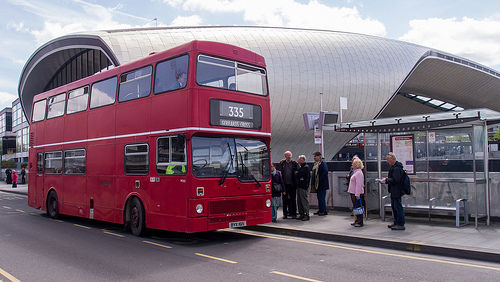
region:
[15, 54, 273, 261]
a red double decker bus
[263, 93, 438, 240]
people at the bus station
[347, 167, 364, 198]
a pink shirt on a woman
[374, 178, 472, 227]
a metal bench at a bus stop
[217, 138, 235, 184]
a windshield wiper on a bus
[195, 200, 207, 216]
a headlight on a bus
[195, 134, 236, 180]
the front window of a bus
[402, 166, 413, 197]
a black backpack on a man's back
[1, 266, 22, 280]
a yellow line in the road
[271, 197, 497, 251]
a sidewalk next to the road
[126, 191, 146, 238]
a black wheel on a bus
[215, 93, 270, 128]
number 335 on top of bus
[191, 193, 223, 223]
headlight on right front of bus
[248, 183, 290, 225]
left front headlight on bus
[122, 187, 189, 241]
right front tire of bus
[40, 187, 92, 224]
right rear tire on bus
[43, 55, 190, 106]
row of upper windows on bus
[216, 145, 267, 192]
black windshield wipers on bus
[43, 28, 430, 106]
large silver building in background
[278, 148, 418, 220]
people standing waiting to get on the bus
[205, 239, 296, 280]
yellow painted lines in middle of road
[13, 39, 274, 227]
tall red bus on road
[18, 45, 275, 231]
two story bus on road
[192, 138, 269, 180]
front window of bus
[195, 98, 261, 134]
numbers on front of bus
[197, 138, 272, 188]
window wipers on bus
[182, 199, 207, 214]
front light of bus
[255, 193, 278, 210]
front light of bus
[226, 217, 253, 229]
license plate on front of bus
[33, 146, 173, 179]
bottom windows on bus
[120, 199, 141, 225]
front black wheel of bus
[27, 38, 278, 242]
red double decker bus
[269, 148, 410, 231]
seven people waiting to board bus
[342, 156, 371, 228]
woman in pink jacket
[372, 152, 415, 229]
man reading while standing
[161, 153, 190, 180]
bus driver wearing a yellow-green jacket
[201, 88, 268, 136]
double decker bus with number 335 on the front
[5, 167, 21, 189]
person standing while wearing a red jacket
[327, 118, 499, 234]
covered bus stop with 3 people waiting for bus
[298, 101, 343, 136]
two cameras watching the street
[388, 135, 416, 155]
sign in a bus stop